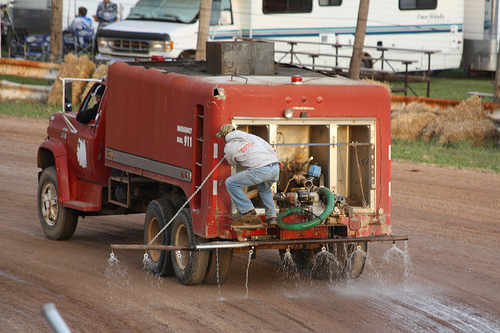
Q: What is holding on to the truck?
A: A man.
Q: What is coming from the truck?
A: Water.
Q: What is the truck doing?
A: Wetting the track.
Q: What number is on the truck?
A: 911.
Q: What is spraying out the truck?
A: Water.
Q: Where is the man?
A: On the back of the truck.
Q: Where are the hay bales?
A: Along the track.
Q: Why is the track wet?
A: It is being sprayed.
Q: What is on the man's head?
A: Baseball cap.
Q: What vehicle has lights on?
A: The white RV.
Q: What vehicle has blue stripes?
A: The white RV.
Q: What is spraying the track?
A: The red truck.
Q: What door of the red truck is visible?
A: The driver's side.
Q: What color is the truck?
A: Red.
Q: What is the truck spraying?
A: Water.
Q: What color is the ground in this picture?
A: Brown.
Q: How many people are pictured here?
A: Three.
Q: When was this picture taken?
A: Daytime.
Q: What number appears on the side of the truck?
A: 911.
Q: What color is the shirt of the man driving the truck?
A: Black.